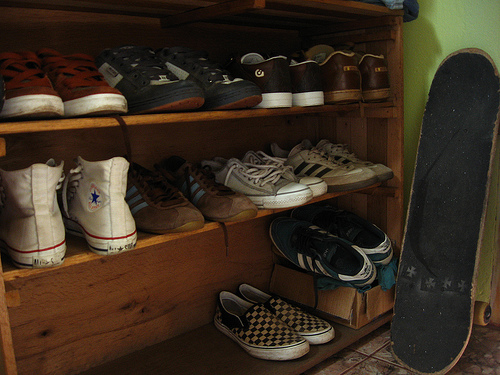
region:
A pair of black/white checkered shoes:
[203, 272, 339, 362]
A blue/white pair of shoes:
[260, 200, 400, 290]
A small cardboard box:
[265, 265, 400, 326]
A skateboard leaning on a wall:
[380, 35, 496, 370]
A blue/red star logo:
[80, 176, 105, 211]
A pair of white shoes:
[0, 150, 140, 281]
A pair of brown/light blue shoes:
[115, 146, 261, 253]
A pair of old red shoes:
[0, 41, 125, 136]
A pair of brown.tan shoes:
[300, 32, 401, 102]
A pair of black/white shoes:
[265, 130, 397, 200]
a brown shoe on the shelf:
[119, 162, 209, 240]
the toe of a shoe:
[164, 205, 214, 237]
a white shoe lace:
[221, 160, 239, 187]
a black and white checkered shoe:
[206, 287, 315, 363]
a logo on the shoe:
[81, 175, 110, 214]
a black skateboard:
[385, 44, 499, 374]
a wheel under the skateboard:
[470, 296, 495, 331]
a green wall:
[403, 0, 498, 301]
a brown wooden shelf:
[0, 174, 390, 284]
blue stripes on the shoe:
[123, 184, 151, 214]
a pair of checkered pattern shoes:
[215, 280, 336, 357]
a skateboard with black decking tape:
[392, 50, 499, 371]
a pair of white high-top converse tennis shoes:
[1, 153, 137, 267]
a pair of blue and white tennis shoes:
[268, 205, 397, 294]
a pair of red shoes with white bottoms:
[4, 29, 128, 119]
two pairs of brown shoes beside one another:
[230, 35, 394, 109]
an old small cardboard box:
[266, 258, 397, 326]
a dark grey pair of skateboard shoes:
[94, 40, 259, 115]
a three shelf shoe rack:
[0, 3, 404, 373]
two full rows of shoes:
[1, 3, 400, 267]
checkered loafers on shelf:
[210, 281, 333, 361]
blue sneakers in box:
[265, 202, 393, 287]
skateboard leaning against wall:
[387, 46, 498, 373]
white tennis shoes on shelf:
[0, 155, 138, 267]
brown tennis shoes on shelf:
[124, 153, 258, 235]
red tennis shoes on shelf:
[0, 48, 130, 113]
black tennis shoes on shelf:
[96, 45, 263, 111]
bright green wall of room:
[402, 0, 498, 313]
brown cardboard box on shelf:
[266, 262, 393, 330]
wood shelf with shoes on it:
[0, 0, 404, 372]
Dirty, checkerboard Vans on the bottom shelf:
[212, 283, 336, 362]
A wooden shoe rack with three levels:
[0, 0, 410, 374]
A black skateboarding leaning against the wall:
[388, 47, 497, 374]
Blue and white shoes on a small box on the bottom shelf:
[268, 203, 394, 291]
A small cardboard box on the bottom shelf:
[266, 263, 394, 329]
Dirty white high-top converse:
[0, 155, 137, 265]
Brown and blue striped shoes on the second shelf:
[121, 155, 259, 234]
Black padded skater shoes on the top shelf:
[95, 42, 263, 112]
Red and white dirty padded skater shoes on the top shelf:
[0, 49, 129, 117]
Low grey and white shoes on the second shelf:
[201, 152, 325, 207]